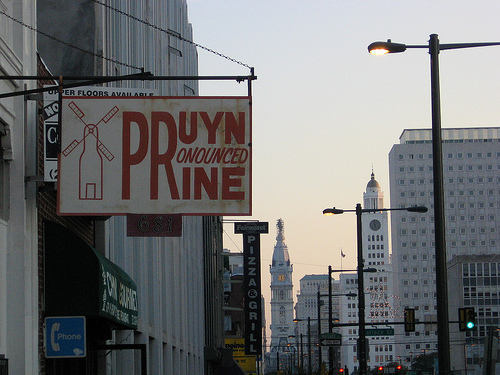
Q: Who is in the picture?
A: No one.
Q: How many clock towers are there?
A: Two.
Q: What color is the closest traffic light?
A: Green.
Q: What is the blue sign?
A: Phone.